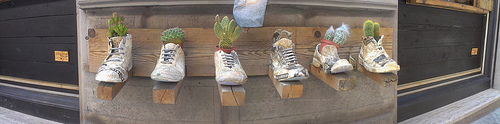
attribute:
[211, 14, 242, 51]
tree — small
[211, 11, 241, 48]
plant — potted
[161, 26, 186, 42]
tree — small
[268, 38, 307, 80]
sneaker — black, white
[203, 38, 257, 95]
plant pots — shoe shaped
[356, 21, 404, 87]
plant pots — shoe shaped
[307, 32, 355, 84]
plant pots — shoe shaped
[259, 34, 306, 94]
plant pots — shoe shaped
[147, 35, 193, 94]
plant pots — shoe shaped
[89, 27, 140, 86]
plant pots — shoe shaped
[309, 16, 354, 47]
cactus — blue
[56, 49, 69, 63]
plaque — small, rectangular, gold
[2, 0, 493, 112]
background — black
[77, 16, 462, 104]
shoe — white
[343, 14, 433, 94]
pot — clay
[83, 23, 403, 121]
display — unique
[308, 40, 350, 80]
sneaker — white, black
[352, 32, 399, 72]
sneaker — white, black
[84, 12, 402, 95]
display — wooden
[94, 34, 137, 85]
sneaker — high top